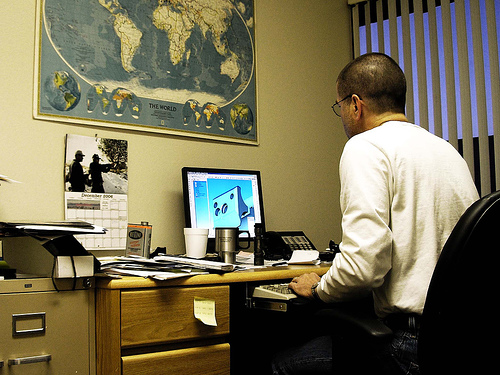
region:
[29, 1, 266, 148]
rectangular blue and white map on wall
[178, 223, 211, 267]
white styrofoam cup on wooden desk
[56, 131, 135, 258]
white and black calendar on wall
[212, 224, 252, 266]
silver and black metal coffee cup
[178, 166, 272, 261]
black flat screen computer monitor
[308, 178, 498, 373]
black desk chair next to wooden desk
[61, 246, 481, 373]
light brown wooden desk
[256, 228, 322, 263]
black phone on wooden desk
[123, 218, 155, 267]
metal can on wooden desk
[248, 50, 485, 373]
man wearing white shirt and jeans sitting at desk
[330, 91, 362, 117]
the glasses on the man's face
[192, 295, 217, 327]
the piece of post it paper on the drawer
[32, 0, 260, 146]
the map hanging on the wall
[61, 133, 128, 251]
the calendar hanging on the wall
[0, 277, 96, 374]
the file cabinet next to the desk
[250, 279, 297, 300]
the computer's keyboard on the desks pull out tray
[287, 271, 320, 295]
the hand on the keyboard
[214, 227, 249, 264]
the silver cup on the desk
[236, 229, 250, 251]
the handle on the silver cup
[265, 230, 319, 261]
the phone on the desk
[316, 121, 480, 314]
Man sitting at his desk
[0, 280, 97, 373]
A file cabinet against the wall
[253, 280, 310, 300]
Computer keyboard used by the man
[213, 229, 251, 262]
Stainless steel coffee cup sitting on the desk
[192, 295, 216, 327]
Note-it taped to desk drawer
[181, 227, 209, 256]
White styrofoam cup sitting on the dest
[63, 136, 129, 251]
Calendar hanging on the wall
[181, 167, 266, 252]
computer monitor sitting on the desk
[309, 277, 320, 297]
Watch on man's left wrist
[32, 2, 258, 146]
Map of the world hanging on the wall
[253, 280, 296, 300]
a beige computer keyboard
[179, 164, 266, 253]
a black computer monitor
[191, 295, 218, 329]
a yellow sticky note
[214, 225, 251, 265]
a travel coffee mug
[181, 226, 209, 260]
a white foam cup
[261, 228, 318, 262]
a black telephone set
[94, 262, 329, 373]
a light brown desk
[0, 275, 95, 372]
a tan filing cabinet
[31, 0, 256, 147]
a map of the world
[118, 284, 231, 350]
a wood desk drawer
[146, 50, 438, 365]
the man is working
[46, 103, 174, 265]
calendar on the wall